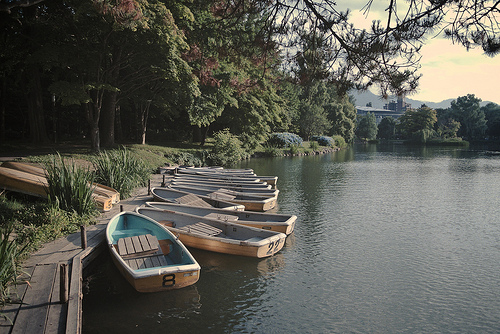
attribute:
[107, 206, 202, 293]
boat — wooden, white, tied up, small, tied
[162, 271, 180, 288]
part — black, number 8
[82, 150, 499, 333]
water — green, calm, small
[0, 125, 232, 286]
terrain — hilly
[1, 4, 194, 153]
tree — green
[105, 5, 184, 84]
leaves — green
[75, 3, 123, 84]
leaves — green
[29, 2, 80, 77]
leaves — green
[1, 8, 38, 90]
leaves — green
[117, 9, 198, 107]
leaves — green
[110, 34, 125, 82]
branch — brown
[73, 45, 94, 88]
branch — brown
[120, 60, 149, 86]
branch — brown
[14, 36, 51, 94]
branch — brown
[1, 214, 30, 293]
plantations — green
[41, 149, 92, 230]
plantations — green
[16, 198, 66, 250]
plantations — green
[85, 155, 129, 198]
plantations — green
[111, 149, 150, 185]
plantations — green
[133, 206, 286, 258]
boat — wooden, gray, tied up, small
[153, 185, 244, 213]
boat — tied up, small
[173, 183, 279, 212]
boat — tied up, small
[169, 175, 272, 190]
boat — small, tied up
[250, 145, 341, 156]
bridge — rocked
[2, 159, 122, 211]
walkway — wooden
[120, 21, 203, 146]
tree — green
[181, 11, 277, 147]
tree — green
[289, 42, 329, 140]
tree — green